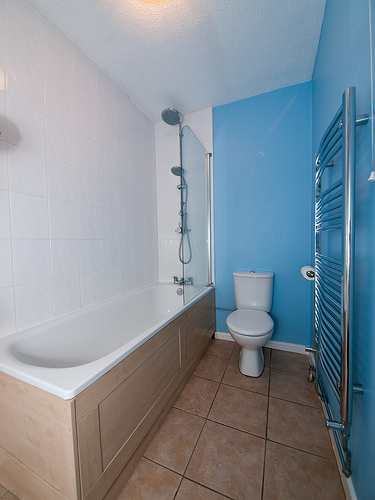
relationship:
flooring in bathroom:
[104, 336, 349, 498] [1, 0, 371, 498]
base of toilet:
[233, 345, 266, 377] [222, 306, 279, 385]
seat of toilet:
[224, 307, 274, 337] [203, 241, 290, 410]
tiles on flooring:
[153, 348, 373, 496] [104, 336, 349, 498]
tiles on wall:
[6, 6, 185, 339] [1, 0, 213, 335]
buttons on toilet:
[247, 266, 260, 278] [212, 258, 296, 361]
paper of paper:
[301, 265, 315, 281] [300, 265, 314, 282]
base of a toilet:
[239, 346, 267, 377] [219, 267, 290, 386]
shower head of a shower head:
[161, 108, 181, 125] [160, 107, 183, 124]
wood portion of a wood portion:
[72, 285, 216, 497] [0, 371, 80, 498]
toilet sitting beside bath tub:
[228, 255, 284, 368] [0, 283, 215, 499]